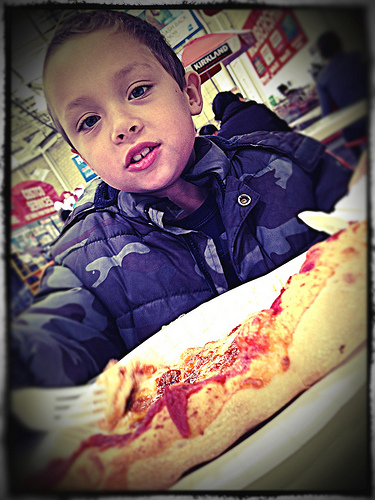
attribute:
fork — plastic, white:
[18, 376, 93, 427]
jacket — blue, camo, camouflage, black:
[45, 176, 316, 331]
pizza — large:
[97, 312, 374, 461]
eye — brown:
[126, 84, 158, 104]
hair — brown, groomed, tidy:
[52, 12, 208, 80]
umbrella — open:
[180, 34, 254, 74]